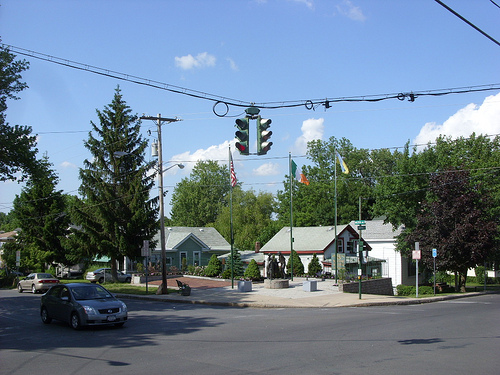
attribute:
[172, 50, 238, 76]
cloud — small, fluffy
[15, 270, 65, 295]
car — sand, colored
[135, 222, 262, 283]
house — green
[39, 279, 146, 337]
car — silver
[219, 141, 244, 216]
light — red